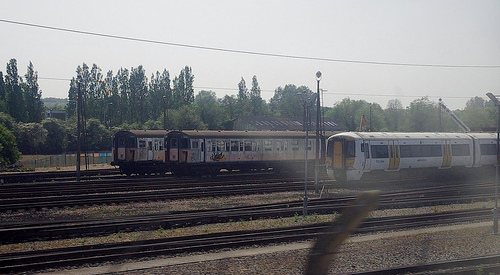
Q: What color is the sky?
A: Gray.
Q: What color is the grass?
A: Green.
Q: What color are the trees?
A: Green.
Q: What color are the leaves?
A: Green.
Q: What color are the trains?
A: White.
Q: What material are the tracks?
A: Metal.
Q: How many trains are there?
A: 3.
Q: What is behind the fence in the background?
A: Trees.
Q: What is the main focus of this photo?
A: Trains.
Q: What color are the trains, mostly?
A: White.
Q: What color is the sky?
A: Grey-white.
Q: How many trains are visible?
A: Three.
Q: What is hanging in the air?
A: Cables.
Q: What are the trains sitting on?
A: Train tracks.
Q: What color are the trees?
A: Green.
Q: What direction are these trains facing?
A: Left.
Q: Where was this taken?
A: Train yard.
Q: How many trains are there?
A: 3.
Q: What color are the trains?
A: White.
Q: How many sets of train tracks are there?
A: 5.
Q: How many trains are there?
A: 3.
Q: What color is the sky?
A: Gray.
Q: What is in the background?
A: Trees.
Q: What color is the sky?
A: Gray.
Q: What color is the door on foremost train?
A: Light brown.